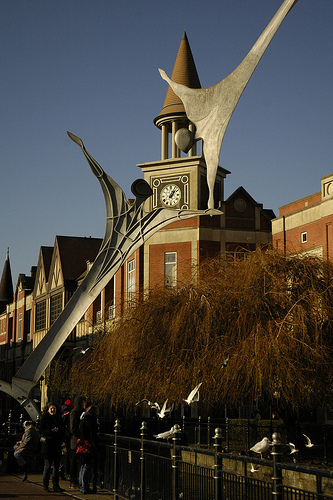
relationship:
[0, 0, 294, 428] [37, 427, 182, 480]
sculpture above people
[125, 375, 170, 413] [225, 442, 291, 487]
birds on fence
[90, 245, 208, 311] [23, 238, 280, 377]
windows on buildings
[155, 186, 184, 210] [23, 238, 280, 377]
clock on buildings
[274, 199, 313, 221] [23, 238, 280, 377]
roof on buildings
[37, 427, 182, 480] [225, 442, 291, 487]
people near fence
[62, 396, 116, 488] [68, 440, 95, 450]
woman holding bag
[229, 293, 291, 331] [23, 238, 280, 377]
tree in buildings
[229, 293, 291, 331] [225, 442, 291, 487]
tree near fence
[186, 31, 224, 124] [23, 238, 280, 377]
cone on buildings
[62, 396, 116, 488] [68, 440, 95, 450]
woman carrying bag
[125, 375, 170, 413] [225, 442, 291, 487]
birds near fence